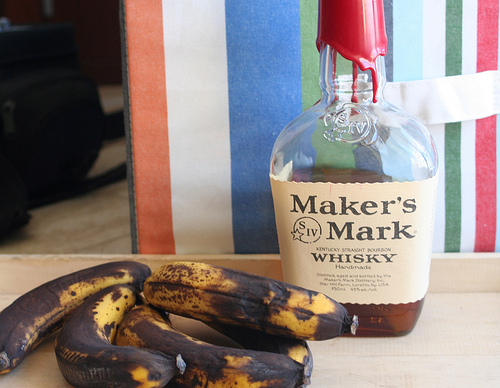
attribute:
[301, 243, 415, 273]
word — whisky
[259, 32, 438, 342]
bottle — glass, clear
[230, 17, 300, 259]
stripe — blue, wide, vertical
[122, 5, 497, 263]
wall — striped, multi colored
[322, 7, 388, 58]
wax — red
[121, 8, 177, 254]
stripe — orange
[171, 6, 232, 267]
stripe — white, wide, vertical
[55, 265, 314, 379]
bananas — rotten, riped, ripened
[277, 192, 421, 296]
label — tan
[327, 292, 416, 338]
whisky — brown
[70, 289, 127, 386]
banana — over riped, riped, bruised, yellow, brown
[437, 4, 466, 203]
stripe — green, narrow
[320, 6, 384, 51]
top — pink, red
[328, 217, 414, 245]
mark — word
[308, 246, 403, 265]
whisky — word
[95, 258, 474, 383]
table — brown, wooden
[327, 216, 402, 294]
text — black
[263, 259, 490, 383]
counter — wooden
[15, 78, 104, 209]
bag — black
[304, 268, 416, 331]
liquor — golden